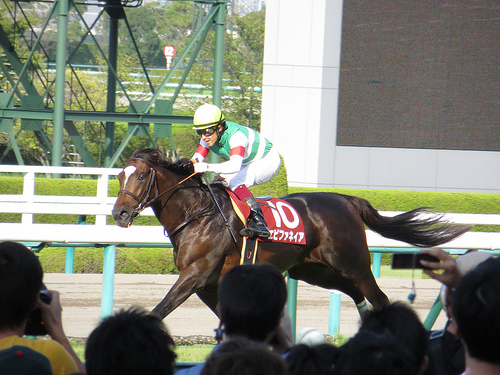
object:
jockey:
[185, 101, 283, 245]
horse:
[108, 144, 473, 325]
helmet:
[188, 102, 228, 135]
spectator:
[218, 266, 291, 343]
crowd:
[0, 241, 499, 374]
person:
[83, 304, 182, 374]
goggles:
[193, 124, 222, 139]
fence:
[0, 235, 497, 339]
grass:
[175, 343, 209, 360]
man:
[0, 238, 86, 374]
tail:
[346, 191, 472, 247]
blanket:
[225, 186, 311, 247]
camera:
[20, 284, 57, 338]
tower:
[2, 0, 230, 179]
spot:
[119, 162, 138, 192]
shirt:
[0, 334, 84, 375]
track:
[41, 273, 461, 334]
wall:
[267, 0, 499, 189]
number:
[266, 197, 303, 231]